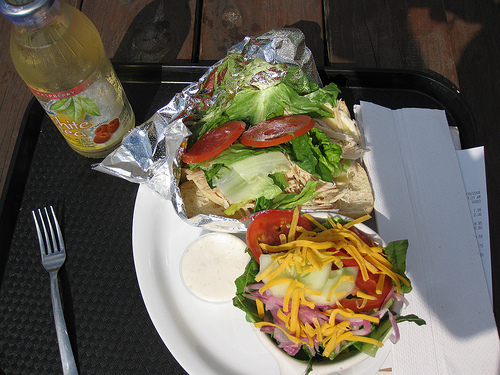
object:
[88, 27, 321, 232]
foil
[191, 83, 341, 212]
lettuce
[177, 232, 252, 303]
cup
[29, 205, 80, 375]
fork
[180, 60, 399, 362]
food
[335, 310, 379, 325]
shredded cheese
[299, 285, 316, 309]
shredded cheese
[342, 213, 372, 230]
shredded cheese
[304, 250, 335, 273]
shredded cheese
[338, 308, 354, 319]
shredded cheese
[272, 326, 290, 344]
cheese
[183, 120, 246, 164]
tomato slice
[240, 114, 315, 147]
tomato slice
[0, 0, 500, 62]
table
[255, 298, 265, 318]
cheese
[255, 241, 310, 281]
shredded cheese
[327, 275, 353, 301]
cheese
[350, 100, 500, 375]
paper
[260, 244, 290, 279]
cheese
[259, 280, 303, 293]
cheese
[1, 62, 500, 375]
black tray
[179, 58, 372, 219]
sandwich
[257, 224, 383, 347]
salad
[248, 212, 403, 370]
bowl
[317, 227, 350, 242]
cheese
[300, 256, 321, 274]
cheese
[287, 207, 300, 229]
cheese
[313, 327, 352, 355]
cheese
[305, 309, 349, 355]
shredded cheese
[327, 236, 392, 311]
tomato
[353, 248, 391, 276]
cheese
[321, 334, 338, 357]
cheese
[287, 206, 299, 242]
piece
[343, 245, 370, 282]
piece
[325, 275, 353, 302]
piece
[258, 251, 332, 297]
piece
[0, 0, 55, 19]
cap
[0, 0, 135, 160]
bottle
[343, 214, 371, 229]
pieces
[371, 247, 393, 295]
pieces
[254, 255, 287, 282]
pieces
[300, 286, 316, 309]
pieces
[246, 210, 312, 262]
tomato